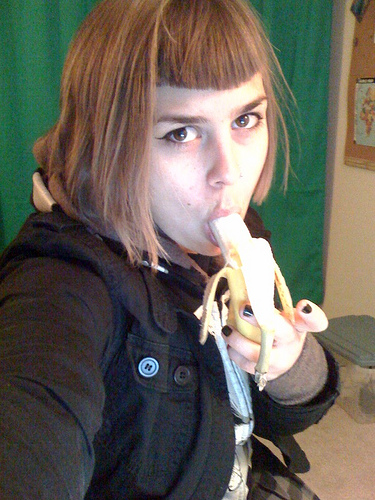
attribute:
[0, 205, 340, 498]
jacket — light-black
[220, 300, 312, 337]
fingernails — black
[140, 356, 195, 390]
buttons — black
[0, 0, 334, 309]
curtain — green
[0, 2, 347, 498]
woman — has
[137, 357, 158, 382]
button — small, black, four-holed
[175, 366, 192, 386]
button — four-holed, small, black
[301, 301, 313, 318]
nails — black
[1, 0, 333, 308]
sheet — green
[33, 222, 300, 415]
jacket — black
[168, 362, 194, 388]
button — black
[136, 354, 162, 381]
button — black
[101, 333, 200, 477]
pocket — flapped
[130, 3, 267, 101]
girl hair — short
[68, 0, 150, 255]
girl hair — short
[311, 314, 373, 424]
bin — small, plastic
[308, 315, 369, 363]
lid — light-blue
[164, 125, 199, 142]
eye — brown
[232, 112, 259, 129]
eye — brown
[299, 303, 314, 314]
nail polish — on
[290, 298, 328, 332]
pointer finger — has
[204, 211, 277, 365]
banana — yellow, peeled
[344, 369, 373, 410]
container — plastic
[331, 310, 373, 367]
lid — gray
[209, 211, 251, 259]
banana — half peeled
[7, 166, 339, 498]
coat — black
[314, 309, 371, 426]
container — plastic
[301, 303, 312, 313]
nail polish — dark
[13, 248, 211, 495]
coat — black